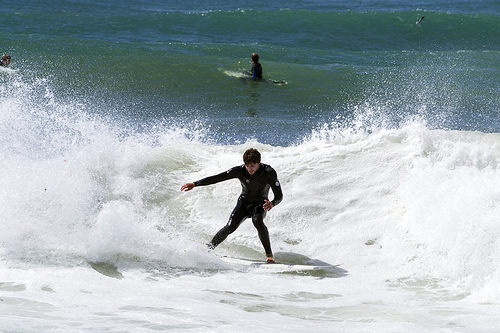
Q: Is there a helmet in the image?
A: No, there are no helmets.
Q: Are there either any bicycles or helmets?
A: No, there are no helmets or bicycles.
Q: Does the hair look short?
A: Yes, the hair is short.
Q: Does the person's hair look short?
A: Yes, the hair is short.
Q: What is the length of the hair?
A: The hair is short.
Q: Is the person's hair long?
A: No, the hair is short.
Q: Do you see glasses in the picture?
A: No, there are no glasses.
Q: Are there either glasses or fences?
A: No, there are no glasses or fences.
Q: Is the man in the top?
A: Yes, the man is in the top of the image.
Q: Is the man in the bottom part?
A: No, the man is in the top of the image.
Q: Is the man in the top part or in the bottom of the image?
A: The man is in the top of the image.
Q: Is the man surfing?
A: Yes, the man is surfing.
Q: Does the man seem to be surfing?
A: Yes, the man is surfing.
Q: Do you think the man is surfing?
A: Yes, the man is surfing.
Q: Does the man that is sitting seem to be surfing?
A: Yes, the man is surfing.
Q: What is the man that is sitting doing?
A: The man is surfing.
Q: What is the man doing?
A: The man is surfing.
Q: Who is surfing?
A: The man is surfing.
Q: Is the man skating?
A: No, the man is surfing.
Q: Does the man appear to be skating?
A: No, the man is surfing.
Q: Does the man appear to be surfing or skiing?
A: The man is surfing.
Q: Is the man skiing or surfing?
A: The man is surfing.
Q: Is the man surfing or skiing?
A: The man is surfing.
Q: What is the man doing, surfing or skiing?
A: The man is surfing.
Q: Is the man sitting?
A: Yes, the man is sitting.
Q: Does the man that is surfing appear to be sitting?
A: Yes, the man is sitting.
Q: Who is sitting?
A: The man is sitting.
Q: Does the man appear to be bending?
A: No, the man is sitting.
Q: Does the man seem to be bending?
A: No, the man is sitting.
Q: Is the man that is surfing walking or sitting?
A: The man is sitting.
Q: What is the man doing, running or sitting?
A: The man is sitting.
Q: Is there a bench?
A: No, there are no benches.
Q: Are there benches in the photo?
A: No, there are no benches.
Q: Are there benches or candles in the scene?
A: No, there are no benches or candles.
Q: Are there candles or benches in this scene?
A: No, there are no benches or candles.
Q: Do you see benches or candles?
A: No, there are no benches or candles.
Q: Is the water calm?
A: Yes, the water is calm.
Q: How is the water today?
A: The water is calm.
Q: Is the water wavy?
A: No, the water is calm.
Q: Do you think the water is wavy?
A: No, the water is calm.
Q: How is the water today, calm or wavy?
A: The water is calm.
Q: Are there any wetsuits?
A: Yes, there is a wetsuit.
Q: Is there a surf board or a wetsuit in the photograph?
A: Yes, there is a wetsuit.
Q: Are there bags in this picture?
A: No, there are no bags.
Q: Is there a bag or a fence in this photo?
A: No, there are no bags or fences.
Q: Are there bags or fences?
A: No, there are no bags or fences.